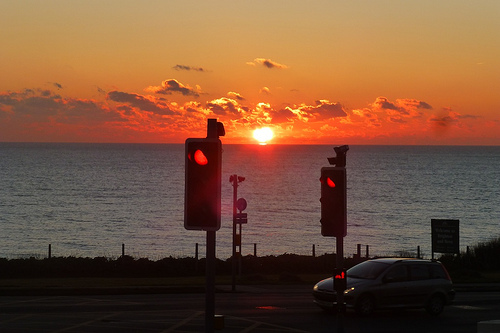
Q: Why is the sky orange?
A: It's sunset.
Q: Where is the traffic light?
A: On the road.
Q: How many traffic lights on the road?
A: Two.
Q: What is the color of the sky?
A: Orange and yellow.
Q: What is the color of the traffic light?
A: Red.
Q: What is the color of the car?
A: Black.